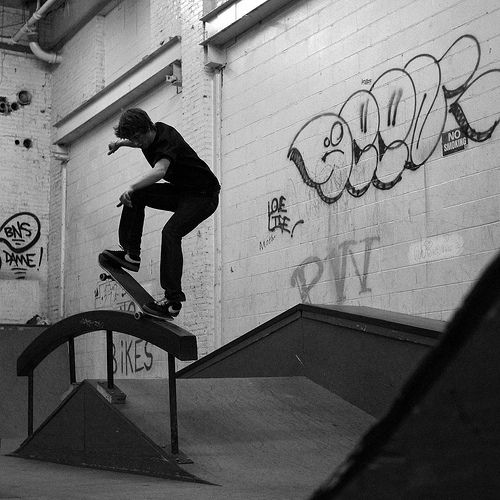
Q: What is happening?
A: Skateboarding.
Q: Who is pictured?
A: A skateboarder.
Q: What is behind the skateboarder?
A: A wall with graffiti.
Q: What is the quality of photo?
A: Black and white and in focus.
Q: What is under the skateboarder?
A: A skate ramp.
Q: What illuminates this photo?
A: Indoor lighting.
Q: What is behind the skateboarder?
A: A brick wall.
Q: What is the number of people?
A: One.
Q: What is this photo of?
A: A man.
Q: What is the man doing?
A: Skateboarding.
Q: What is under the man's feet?
A: A skateboard.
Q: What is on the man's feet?
A: Sneakers.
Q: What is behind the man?
A: A wall.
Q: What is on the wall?
A: Graffiti.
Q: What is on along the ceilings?
A: Pipes.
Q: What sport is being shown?
A: Skateboarding.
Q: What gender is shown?
A: A male.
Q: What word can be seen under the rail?
A: Bikes.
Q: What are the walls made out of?
A: Brick.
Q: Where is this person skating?
A: A skatepark.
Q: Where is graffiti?
A: On the walls.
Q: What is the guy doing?
A: Skateboarding.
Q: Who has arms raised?
A: The skateboarder.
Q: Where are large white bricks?
A: On the walls.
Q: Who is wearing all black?
A: Guy skateboarding.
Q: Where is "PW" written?
A: On the wall.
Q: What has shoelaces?
A: Sneakers.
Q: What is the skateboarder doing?
A: Performing a trick.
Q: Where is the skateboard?
A: Under the guy's feet.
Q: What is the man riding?
A: The skateboard.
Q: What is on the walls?
A: Graffiti.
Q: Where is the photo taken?
A: At a skatepark.